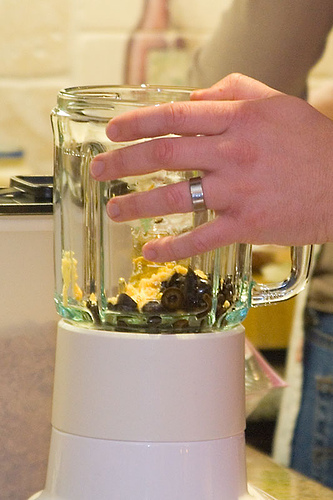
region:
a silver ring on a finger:
[188, 176, 205, 205]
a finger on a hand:
[142, 212, 232, 264]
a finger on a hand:
[107, 177, 232, 217]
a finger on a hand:
[89, 137, 216, 172]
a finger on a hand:
[107, 95, 231, 135]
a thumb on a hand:
[193, 68, 261, 100]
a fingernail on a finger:
[143, 244, 155, 259]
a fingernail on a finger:
[106, 198, 119, 216]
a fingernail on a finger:
[90, 153, 103, 173]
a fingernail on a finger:
[104, 121, 117, 137]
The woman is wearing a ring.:
[183, 176, 226, 217]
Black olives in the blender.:
[138, 262, 207, 307]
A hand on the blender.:
[60, 116, 275, 238]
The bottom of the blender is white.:
[41, 307, 269, 475]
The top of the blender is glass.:
[46, 85, 279, 322]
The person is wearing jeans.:
[291, 311, 329, 459]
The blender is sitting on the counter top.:
[248, 440, 319, 496]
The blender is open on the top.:
[35, 62, 220, 121]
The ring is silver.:
[183, 170, 216, 211]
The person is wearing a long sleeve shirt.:
[200, 17, 305, 84]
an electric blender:
[32, 81, 312, 496]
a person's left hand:
[90, 74, 331, 256]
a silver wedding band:
[182, 173, 207, 214]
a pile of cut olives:
[103, 265, 226, 331]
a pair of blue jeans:
[290, 297, 331, 478]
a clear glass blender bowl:
[36, 78, 314, 342]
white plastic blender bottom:
[25, 320, 268, 496]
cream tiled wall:
[3, 1, 81, 151]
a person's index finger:
[91, 103, 228, 140]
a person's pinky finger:
[136, 209, 233, 265]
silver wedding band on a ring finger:
[178, 173, 215, 221]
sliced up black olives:
[100, 264, 243, 335]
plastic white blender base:
[31, 310, 273, 499]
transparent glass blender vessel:
[29, 76, 318, 349]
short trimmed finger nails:
[86, 115, 157, 267]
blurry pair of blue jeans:
[289, 300, 332, 491]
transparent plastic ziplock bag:
[231, 328, 289, 423]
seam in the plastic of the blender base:
[44, 414, 260, 453]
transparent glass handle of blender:
[244, 234, 321, 316]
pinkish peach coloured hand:
[83, 71, 330, 286]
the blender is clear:
[20, 42, 273, 368]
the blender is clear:
[43, 104, 226, 302]